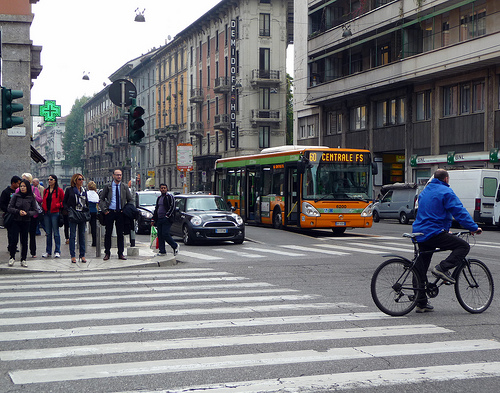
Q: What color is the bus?
A: Orange.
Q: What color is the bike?
A: Black.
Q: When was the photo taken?
A: Day time.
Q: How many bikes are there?
A: One.